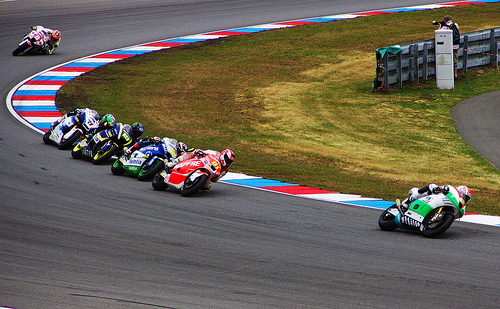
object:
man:
[430, 16, 463, 68]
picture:
[419, 14, 454, 82]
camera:
[432, 19, 440, 29]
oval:
[82, 22, 499, 210]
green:
[376, 171, 459, 241]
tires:
[371, 192, 448, 237]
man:
[451, 180, 471, 204]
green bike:
[442, 180, 467, 214]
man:
[216, 142, 233, 173]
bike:
[203, 142, 234, 172]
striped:
[12, 68, 56, 119]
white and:
[129, 34, 171, 50]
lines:
[124, 33, 147, 55]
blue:
[234, 26, 254, 36]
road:
[239, 26, 259, 34]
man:
[442, 30, 455, 53]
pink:
[436, 25, 458, 49]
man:
[12, 19, 73, 55]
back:
[8, 25, 56, 60]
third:
[126, 130, 171, 177]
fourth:
[99, 121, 130, 162]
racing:
[42, 118, 239, 195]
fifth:
[53, 105, 91, 151]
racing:
[48, 94, 87, 145]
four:
[52, 102, 236, 195]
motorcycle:
[12, 17, 63, 60]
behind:
[17, 18, 70, 64]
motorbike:
[173, 149, 213, 195]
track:
[169, 150, 212, 194]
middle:
[128, 130, 161, 191]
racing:
[128, 130, 166, 187]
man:
[426, 16, 453, 33]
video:
[430, 9, 449, 32]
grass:
[208, 57, 266, 119]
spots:
[12, 148, 46, 192]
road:
[17, 155, 64, 207]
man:
[130, 118, 142, 135]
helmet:
[130, 117, 141, 135]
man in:
[100, 107, 113, 126]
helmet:
[100, 107, 113, 129]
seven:
[19, 16, 474, 212]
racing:
[10, 12, 467, 213]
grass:
[62, 86, 89, 105]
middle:
[254, 57, 294, 76]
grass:
[240, 50, 282, 88]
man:
[430, 14, 462, 88]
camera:
[432, 12, 464, 90]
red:
[177, 144, 239, 207]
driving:
[173, 146, 231, 194]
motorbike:
[376, 167, 470, 244]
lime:
[120, 139, 160, 178]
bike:
[114, 150, 154, 176]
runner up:
[122, 135, 169, 184]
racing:
[52, 97, 139, 175]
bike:
[2, 24, 74, 64]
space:
[240, 162, 371, 229]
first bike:
[241, 155, 381, 231]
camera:
[425, 18, 446, 32]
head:
[455, 176, 470, 200]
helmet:
[452, 180, 470, 202]